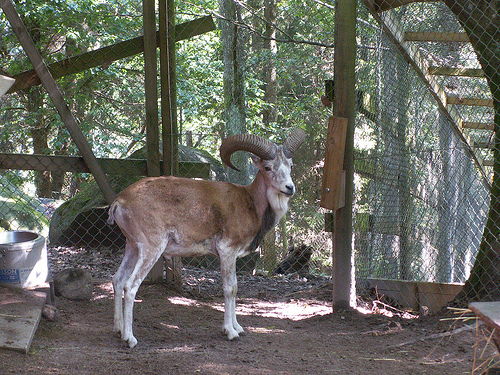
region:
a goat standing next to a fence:
[98, 129, 317, 347]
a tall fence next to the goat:
[3, 5, 498, 322]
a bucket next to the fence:
[1, 227, 46, 286]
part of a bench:
[471, 293, 494, 330]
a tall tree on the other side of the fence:
[441, 2, 497, 303]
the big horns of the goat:
[212, 125, 319, 166]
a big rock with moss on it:
[53, 133, 218, 255]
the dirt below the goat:
[56, 298, 420, 373]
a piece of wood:
[0, 286, 41, 366]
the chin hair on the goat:
[262, 194, 298, 217]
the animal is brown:
[78, 105, 321, 373]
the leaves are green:
[76, 20, 205, 120]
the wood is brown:
[323, 23, 364, 308]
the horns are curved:
[210, 112, 320, 207]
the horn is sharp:
[207, 115, 260, 187]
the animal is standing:
[91, 107, 316, 372]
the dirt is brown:
[168, 324, 353, 372]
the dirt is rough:
[282, 324, 395, 373]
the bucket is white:
[3, 222, 71, 298]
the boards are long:
[132, 10, 189, 169]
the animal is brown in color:
[100, 136, 312, 351]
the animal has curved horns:
[100, 130, 307, 370]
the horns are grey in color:
[209, 124, 320, 164]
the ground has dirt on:
[102, 303, 337, 371]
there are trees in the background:
[48, 83, 323, 123]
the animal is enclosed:
[84, 124, 307, 351]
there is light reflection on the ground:
[279, 294, 358, 348]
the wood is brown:
[315, 113, 352, 220]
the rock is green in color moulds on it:
[40, 134, 204, 182]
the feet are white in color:
[98, 273, 263, 344]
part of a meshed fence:
[398, 100, 478, 171]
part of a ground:
[281, 305, 336, 359]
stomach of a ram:
[175, 218, 215, 259]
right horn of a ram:
[235, 131, 266, 156]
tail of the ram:
[104, 204, 116, 234]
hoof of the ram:
[224, 330, 240, 345]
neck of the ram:
[256, 187, 281, 222]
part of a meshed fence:
[399, 148, 457, 215]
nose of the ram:
[283, 180, 295, 192]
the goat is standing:
[97, 110, 319, 359]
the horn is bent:
[204, 105, 273, 180]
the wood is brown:
[134, 1, 202, 161]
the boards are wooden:
[132, 7, 184, 155]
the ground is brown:
[154, 328, 281, 372]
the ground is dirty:
[262, 277, 452, 373]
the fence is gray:
[360, 57, 475, 249]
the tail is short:
[93, 187, 140, 238]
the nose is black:
[285, 182, 299, 199]